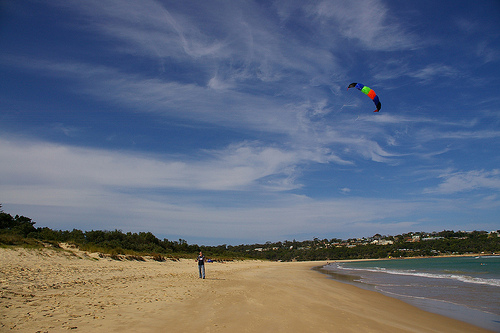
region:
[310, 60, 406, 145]
object in the air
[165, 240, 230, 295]
person on the beach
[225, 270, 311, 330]
brown sand of the beach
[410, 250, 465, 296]
white wave approaching the shore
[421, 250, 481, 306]
ocean next to beach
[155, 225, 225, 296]
person flying an object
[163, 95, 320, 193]
clouds in the sky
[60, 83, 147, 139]
blue sky behind clouds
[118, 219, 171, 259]
green trees in distance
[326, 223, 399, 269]
houses amongst the trees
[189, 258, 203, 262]
Person wearing dark shirt.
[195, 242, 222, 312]
Person wearing jeans.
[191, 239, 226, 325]
Person walking on sandy beach.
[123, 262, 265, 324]
Sand on beach is tan in color.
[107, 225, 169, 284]
Greenery near beach area.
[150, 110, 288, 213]
White wispy clouds in the sky.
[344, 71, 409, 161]
Multi colored kite in sky.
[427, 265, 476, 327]
Water is blue in ocean.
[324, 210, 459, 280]
Houses in the distance.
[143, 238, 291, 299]
Person is flying kite on beach.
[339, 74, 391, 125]
kite in the sky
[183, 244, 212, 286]
person on beach flying a kite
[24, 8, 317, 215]
blue cloudy sky in the distance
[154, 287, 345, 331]
sandy beach where man is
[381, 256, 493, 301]
water of an ocean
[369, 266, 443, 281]
waves rolling in from ocean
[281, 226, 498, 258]
land on side of the beach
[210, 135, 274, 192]
white clouds in the sky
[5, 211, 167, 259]
grassy area by beach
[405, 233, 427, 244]
building in the hills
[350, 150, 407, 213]
part of the sky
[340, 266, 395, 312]
edge of a shore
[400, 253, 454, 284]
part of a water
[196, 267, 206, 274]
part of a trouser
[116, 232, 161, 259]
part of a forest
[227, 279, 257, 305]
part of a beach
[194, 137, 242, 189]
part of a cloud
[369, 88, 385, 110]
part of a parachute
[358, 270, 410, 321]
edge of a shore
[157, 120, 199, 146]
part of the sky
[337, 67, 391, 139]
multicolored kite is flying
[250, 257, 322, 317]
brown sand of shore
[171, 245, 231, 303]
man flying kite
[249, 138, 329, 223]
string of kite man is using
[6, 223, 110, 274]
trees of beach in back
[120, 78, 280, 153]
blue sky for today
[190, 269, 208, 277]
jeans and shoes of man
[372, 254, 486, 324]
waves of ocean on right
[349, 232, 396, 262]
big building in distance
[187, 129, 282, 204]
clouds in the sky